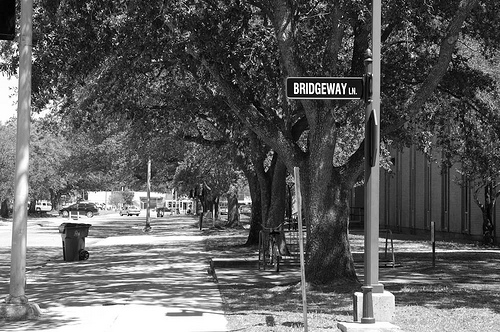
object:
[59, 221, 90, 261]
can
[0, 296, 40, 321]
base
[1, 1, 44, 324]
light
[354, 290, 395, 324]
block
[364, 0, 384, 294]
post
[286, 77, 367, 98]
sign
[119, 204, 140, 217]
car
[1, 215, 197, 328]
road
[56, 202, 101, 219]
car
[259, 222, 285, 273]
bicycle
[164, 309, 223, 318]
shadows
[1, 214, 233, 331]
sidewalk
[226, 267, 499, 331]
grass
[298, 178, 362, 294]
trunk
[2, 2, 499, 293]
tree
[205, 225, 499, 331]
yard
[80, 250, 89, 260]
wheels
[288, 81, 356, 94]
lettering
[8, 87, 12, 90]
leaves